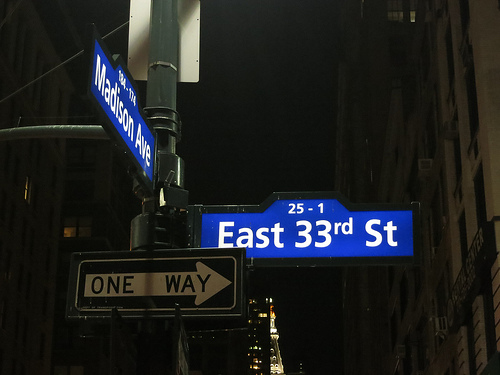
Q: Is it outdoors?
A: Yes, it is outdoors.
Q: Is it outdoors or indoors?
A: It is outdoors.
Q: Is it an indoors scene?
A: No, it is outdoors.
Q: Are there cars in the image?
A: No, there are no cars.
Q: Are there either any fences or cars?
A: No, there are no cars or fences.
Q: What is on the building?
A: The sign is on the building.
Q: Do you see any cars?
A: No, there are no cars.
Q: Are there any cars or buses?
A: No, there are no cars or buses.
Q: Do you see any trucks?
A: No, there are no trucks.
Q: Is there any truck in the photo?
A: No, there are no trucks.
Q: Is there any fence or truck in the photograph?
A: No, there are no trucks or fences.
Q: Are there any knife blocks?
A: No, there are no knife blocks.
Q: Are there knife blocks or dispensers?
A: No, there are no knife blocks or dispensers.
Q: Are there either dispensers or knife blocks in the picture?
A: No, there are no knife blocks or dispensers.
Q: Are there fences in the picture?
A: No, there are no fences.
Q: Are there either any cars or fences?
A: No, there are no fences or cars.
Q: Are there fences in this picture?
A: No, there are no fences.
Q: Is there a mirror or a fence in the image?
A: No, there are no fences or mirrors.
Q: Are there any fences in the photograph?
A: No, there are no fences.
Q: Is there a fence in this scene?
A: No, there are no fences.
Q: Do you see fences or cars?
A: No, there are no fences or cars.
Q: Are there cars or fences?
A: No, there are no fences or cars.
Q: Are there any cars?
A: No, there are no cars.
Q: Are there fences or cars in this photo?
A: No, there are no cars or fences.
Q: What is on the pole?
A: The sign is on the pole.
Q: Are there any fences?
A: No, there are no fences.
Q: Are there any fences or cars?
A: No, there are no fences or cars.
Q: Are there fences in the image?
A: No, there are no fences.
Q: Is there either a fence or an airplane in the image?
A: No, there are no fences or airplanes.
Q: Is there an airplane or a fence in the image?
A: No, there are no fences or airplanes.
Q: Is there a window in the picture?
A: Yes, there is a window.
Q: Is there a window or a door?
A: Yes, there is a window.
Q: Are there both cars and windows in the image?
A: No, there is a window but no cars.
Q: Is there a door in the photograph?
A: No, there are no doors.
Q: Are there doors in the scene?
A: No, there are no doors.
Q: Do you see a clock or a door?
A: No, there are no doors or clocks.